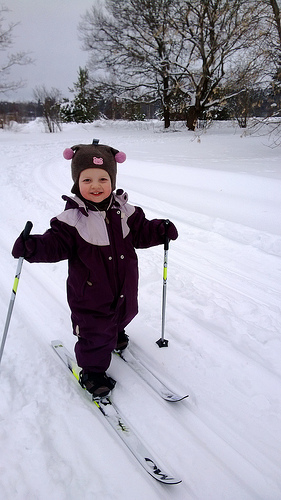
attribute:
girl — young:
[11, 134, 184, 406]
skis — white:
[48, 315, 201, 491]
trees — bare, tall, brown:
[2, 2, 280, 149]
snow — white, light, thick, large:
[3, 110, 280, 499]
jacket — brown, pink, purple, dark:
[21, 185, 169, 301]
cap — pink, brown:
[61, 142, 125, 191]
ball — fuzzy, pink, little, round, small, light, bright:
[62, 145, 74, 160]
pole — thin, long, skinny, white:
[153, 220, 177, 350]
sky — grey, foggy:
[3, 1, 280, 105]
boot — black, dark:
[73, 363, 120, 398]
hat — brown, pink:
[59, 133, 127, 171]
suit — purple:
[6, 190, 172, 373]